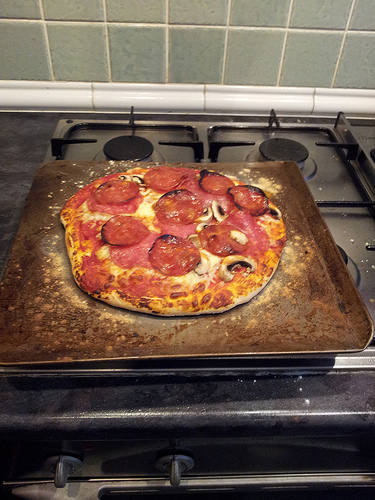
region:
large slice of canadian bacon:
[143, 234, 201, 279]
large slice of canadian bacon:
[102, 215, 143, 243]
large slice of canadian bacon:
[97, 178, 133, 204]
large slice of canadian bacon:
[233, 185, 262, 212]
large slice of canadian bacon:
[167, 188, 202, 220]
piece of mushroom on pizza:
[214, 199, 223, 222]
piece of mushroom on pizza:
[221, 256, 251, 274]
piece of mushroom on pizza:
[266, 205, 278, 217]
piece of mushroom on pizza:
[134, 174, 148, 187]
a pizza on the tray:
[53, 132, 372, 376]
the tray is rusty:
[39, 169, 309, 332]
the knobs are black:
[37, 455, 198, 483]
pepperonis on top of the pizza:
[69, 158, 286, 301]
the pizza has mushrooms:
[185, 202, 247, 301]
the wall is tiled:
[30, 16, 367, 99]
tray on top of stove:
[5, 110, 341, 373]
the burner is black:
[72, 119, 332, 167]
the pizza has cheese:
[47, 163, 330, 371]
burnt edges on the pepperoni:
[86, 213, 152, 254]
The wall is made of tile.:
[14, 4, 355, 71]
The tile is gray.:
[16, 6, 324, 70]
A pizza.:
[55, 161, 294, 319]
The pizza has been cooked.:
[50, 159, 296, 341]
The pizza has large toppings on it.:
[135, 224, 207, 286]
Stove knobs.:
[11, 432, 224, 498]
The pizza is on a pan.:
[4, 153, 374, 363]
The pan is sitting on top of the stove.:
[0, 153, 373, 390]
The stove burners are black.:
[39, 98, 372, 224]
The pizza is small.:
[50, 160, 301, 335]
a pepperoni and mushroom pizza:
[91, 171, 272, 306]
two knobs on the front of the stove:
[28, 442, 224, 495]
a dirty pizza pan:
[19, 308, 361, 362]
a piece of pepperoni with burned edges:
[226, 185, 264, 213]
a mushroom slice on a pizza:
[219, 251, 252, 281]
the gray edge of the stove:
[220, 394, 342, 448]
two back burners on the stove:
[73, 113, 341, 163]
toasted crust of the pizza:
[149, 287, 241, 313]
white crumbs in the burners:
[342, 234, 373, 273]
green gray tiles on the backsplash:
[83, 8, 301, 83]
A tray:
[231, 335, 292, 383]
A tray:
[267, 345, 275, 356]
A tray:
[321, 306, 357, 398]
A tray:
[290, 305, 324, 404]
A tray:
[253, 328, 289, 393]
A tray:
[272, 304, 320, 432]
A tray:
[256, 291, 275, 357]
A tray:
[270, 342, 301, 381]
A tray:
[303, 245, 372, 403]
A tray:
[257, 282, 338, 393]